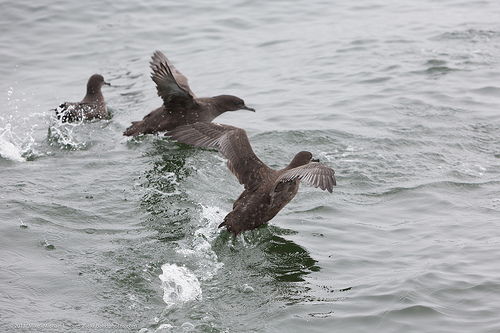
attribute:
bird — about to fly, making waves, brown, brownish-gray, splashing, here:
[164, 120, 337, 239]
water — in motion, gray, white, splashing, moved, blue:
[0, 3, 499, 331]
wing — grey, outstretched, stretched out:
[271, 162, 338, 197]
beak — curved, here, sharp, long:
[312, 156, 321, 163]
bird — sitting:
[53, 73, 113, 124]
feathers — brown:
[150, 59, 176, 82]